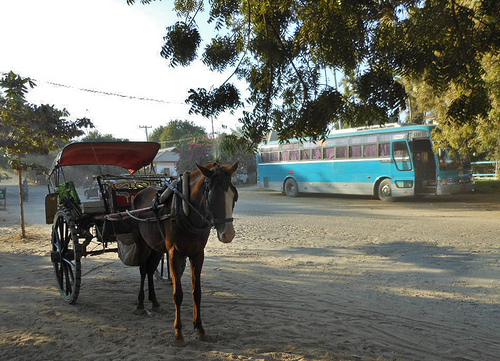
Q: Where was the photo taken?
A: It was taken at the road.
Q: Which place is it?
A: It is a road.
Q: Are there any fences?
A: No, there are no fences.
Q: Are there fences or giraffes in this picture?
A: No, there are no fences or giraffes.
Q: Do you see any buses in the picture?
A: Yes, there is a bus.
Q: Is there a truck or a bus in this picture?
A: Yes, there is a bus.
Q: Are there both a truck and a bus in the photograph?
A: No, there is a bus but no trucks.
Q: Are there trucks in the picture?
A: No, there are no trucks.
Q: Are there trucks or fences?
A: No, there are no trucks or fences.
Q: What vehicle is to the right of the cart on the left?
A: The vehicle is a bus.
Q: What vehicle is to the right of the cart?
A: The vehicle is a bus.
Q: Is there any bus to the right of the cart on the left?
A: Yes, there is a bus to the right of the cart.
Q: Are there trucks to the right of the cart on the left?
A: No, there is a bus to the right of the cart.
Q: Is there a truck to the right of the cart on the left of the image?
A: No, there is a bus to the right of the cart.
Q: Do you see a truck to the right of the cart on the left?
A: No, there is a bus to the right of the cart.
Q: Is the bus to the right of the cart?
A: Yes, the bus is to the right of the cart.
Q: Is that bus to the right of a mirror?
A: No, the bus is to the right of the cart.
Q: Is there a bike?
A: No, there are no bikes.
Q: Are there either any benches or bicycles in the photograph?
A: No, there are no bicycles or benches.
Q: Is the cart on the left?
A: Yes, the cart is on the left of the image.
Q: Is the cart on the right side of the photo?
A: No, the cart is on the left of the image.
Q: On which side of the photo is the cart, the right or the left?
A: The cart is on the left of the image.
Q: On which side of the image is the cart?
A: The cart is on the left of the image.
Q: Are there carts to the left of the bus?
A: Yes, there is a cart to the left of the bus.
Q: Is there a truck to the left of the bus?
A: No, there is a cart to the left of the bus.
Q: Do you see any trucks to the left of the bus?
A: No, there is a cart to the left of the bus.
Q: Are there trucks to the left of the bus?
A: No, there is a cart to the left of the bus.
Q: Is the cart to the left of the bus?
A: Yes, the cart is to the left of the bus.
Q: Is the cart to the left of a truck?
A: No, the cart is to the left of the bus.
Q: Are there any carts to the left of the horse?
A: Yes, there is a cart to the left of the horse.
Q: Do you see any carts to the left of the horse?
A: Yes, there is a cart to the left of the horse.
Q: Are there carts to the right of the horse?
A: No, the cart is to the left of the horse.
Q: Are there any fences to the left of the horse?
A: No, there is a cart to the left of the horse.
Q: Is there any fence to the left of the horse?
A: No, there is a cart to the left of the horse.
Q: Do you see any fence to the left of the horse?
A: No, there is a cart to the left of the horse.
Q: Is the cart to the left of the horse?
A: Yes, the cart is to the left of the horse.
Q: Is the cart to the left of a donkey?
A: No, the cart is to the left of the horse.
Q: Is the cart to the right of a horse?
A: No, the cart is to the left of a horse.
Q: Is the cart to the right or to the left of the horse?
A: The cart is to the left of the horse.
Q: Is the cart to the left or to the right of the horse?
A: The cart is to the left of the horse.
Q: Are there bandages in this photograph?
A: No, there are no bandages.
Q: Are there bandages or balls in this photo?
A: No, there are no bandages or balls.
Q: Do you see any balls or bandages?
A: No, there are no bandages or balls.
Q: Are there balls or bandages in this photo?
A: No, there are no bandages or balls.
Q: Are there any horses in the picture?
A: Yes, there is a horse.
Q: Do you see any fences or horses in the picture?
A: Yes, there is a horse.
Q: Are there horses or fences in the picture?
A: Yes, there is a horse.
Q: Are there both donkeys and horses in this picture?
A: No, there is a horse but no donkeys.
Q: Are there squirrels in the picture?
A: No, there are no squirrels.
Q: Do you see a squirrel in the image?
A: No, there are no squirrels.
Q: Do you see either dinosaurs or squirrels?
A: No, there are no squirrels or dinosaurs.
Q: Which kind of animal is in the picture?
A: The animal is a horse.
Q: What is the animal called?
A: The animal is a horse.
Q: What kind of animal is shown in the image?
A: The animal is a horse.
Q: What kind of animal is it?
A: The animal is a horse.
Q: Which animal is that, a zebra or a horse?
A: That is a horse.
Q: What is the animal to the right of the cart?
A: The animal is a horse.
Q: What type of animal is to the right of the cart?
A: The animal is a horse.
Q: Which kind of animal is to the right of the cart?
A: The animal is a horse.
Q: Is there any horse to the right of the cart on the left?
A: Yes, there is a horse to the right of the cart.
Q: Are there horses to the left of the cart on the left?
A: No, the horse is to the right of the cart.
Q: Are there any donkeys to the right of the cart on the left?
A: No, there is a horse to the right of the cart.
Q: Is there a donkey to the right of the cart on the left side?
A: No, there is a horse to the right of the cart.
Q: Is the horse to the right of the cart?
A: Yes, the horse is to the right of the cart.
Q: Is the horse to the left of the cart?
A: No, the horse is to the right of the cart.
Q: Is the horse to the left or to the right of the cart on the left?
A: The horse is to the right of the cart.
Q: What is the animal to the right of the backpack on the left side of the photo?
A: The animal is a horse.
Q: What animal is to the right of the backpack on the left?
A: The animal is a horse.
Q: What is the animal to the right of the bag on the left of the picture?
A: The animal is a horse.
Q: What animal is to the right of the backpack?
A: The animal is a horse.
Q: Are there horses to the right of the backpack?
A: Yes, there is a horse to the right of the backpack.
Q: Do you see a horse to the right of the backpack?
A: Yes, there is a horse to the right of the backpack.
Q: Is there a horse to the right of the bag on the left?
A: Yes, there is a horse to the right of the backpack.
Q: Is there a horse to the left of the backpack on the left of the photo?
A: No, the horse is to the right of the backpack.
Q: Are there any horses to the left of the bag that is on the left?
A: No, the horse is to the right of the backpack.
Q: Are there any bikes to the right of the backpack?
A: No, there is a horse to the right of the backpack.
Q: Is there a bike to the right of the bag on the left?
A: No, there is a horse to the right of the backpack.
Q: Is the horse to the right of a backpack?
A: Yes, the horse is to the right of a backpack.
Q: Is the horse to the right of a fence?
A: No, the horse is to the right of a backpack.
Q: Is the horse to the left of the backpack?
A: No, the horse is to the right of the backpack.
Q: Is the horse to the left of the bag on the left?
A: No, the horse is to the right of the backpack.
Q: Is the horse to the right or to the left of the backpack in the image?
A: The horse is to the right of the backpack.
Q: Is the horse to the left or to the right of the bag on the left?
A: The horse is to the right of the backpack.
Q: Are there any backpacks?
A: Yes, there is a backpack.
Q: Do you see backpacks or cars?
A: Yes, there is a backpack.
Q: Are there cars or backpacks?
A: Yes, there is a backpack.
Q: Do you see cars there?
A: No, there are no cars.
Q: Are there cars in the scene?
A: No, there are no cars.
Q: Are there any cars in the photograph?
A: No, there are no cars.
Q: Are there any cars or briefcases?
A: No, there are no cars or briefcases.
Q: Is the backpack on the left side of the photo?
A: Yes, the backpack is on the left of the image.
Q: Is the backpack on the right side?
A: No, the backpack is on the left of the image.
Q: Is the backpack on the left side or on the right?
A: The backpack is on the left of the image.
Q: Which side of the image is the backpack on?
A: The backpack is on the left of the image.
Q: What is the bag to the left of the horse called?
A: The bag is a backpack.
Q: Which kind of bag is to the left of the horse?
A: The bag is a backpack.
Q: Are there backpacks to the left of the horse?
A: Yes, there is a backpack to the left of the horse.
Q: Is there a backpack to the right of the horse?
A: No, the backpack is to the left of the horse.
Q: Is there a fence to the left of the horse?
A: No, there is a backpack to the left of the horse.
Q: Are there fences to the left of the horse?
A: No, there is a backpack to the left of the horse.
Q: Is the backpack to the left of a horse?
A: Yes, the backpack is to the left of a horse.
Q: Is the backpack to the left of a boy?
A: No, the backpack is to the left of a horse.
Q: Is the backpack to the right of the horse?
A: No, the backpack is to the left of the horse.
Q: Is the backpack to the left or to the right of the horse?
A: The backpack is to the left of the horse.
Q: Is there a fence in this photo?
A: No, there are no fences.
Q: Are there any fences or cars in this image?
A: No, there are no fences or cars.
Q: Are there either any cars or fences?
A: No, there are no fences or cars.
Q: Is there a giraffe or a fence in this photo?
A: No, there are no fences or giraffes.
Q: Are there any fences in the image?
A: No, there are no fences.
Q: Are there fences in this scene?
A: No, there are no fences.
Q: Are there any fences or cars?
A: No, there are no fences or cars.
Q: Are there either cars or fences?
A: No, there are no fences or cars.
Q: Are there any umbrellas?
A: No, there are no umbrellas.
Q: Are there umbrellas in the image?
A: No, there are no umbrellas.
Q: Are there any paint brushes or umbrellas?
A: No, there are no umbrellas or paint brushes.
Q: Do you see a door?
A: Yes, there is a door.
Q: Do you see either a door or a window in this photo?
A: Yes, there is a door.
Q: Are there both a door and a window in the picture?
A: Yes, there are both a door and a window.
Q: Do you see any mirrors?
A: No, there are no mirrors.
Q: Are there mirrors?
A: No, there are no mirrors.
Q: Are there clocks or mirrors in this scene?
A: No, there are no mirrors or clocks.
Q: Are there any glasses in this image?
A: No, there are no glasses.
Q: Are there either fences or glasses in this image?
A: No, there are no glasses or fences.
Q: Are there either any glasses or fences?
A: No, there are no glasses or fences.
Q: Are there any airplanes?
A: No, there are no airplanes.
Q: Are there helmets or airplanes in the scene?
A: No, there are no airplanes or helmets.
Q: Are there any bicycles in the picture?
A: No, there are no bicycles.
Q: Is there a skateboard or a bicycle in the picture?
A: No, there are no bicycles or skateboards.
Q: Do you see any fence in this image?
A: No, there are no fences.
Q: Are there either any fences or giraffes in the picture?
A: No, there are no fences or giraffes.